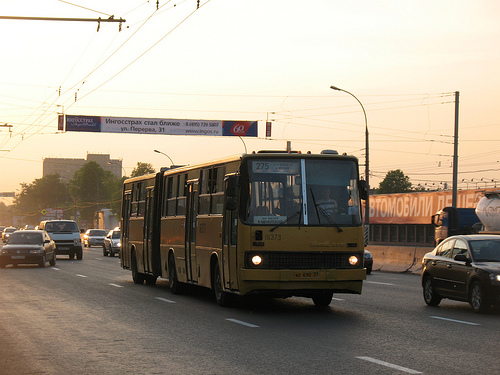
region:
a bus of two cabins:
[111, 160, 363, 302]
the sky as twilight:
[375, 102, 496, 167]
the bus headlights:
[246, 253, 361, 266]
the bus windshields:
[243, 159, 358, 227]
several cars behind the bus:
[6, 220, 124, 263]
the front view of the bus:
[247, 161, 367, 291]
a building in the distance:
[43, 156, 124, 190]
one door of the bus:
[221, 178, 236, 288]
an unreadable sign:
[64, 113, 256, 139]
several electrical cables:
[363, 132, 481, 184]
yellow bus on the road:
[89, 147, 390, 308]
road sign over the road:
[55, 105, 275, 142]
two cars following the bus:
[0, 210, 97, 282]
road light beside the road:
[325, 82, 381, 207]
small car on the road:
[424, 236, 496, 323]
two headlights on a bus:
[246, 253, 358, 273]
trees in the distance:
[11, 166, 132, 210]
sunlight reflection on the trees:
[5, 114, 106, 216]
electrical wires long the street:
[254, 83, 456, 157]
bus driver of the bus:
[317, 184, 338, 210]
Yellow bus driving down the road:
[99, 144, 394, 315]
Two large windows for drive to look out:
[239, 152, 371, 231]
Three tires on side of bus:
[123, 244, 242, 308]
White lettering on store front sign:
[365, 186, 497, 230]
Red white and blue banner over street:
[54, 108, 280, 147]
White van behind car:
[46, 218, 86, 258]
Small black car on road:
[2, 227, 67, 265]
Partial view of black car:
[412, 231, 497, 319]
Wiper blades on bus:
[268, 179, 358, 236]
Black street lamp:
[323, 77, 393, 258]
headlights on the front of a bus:
[243, 250, 363, 277]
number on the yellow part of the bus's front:
[263, 226, 283, 244]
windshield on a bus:
[246, 155, 362, 231]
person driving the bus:
[312, 180, 342, 220]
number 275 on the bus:
[251, 157, 280, 177]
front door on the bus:
[223, 181, 243, 290]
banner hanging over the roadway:
[53, 108, 270, 143]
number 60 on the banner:
[228, 121, 245, 132]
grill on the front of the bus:
[270, 248, 347, 270]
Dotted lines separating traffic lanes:
[32, 248, 416, 373]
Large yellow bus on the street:
[107, 150, 375, 312]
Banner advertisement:
[49, 103, 266, 137]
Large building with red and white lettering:
[347, 168, 482, 279]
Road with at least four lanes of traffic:
[2, 255, 492, 359]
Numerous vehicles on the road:
[3, 206, 125, 263]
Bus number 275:
[242, 151, 277, 175]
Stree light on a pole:
[319, 73, 379, 301]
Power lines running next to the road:
[0, 11, 219, 149]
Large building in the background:
[32, 153, 127, 235]